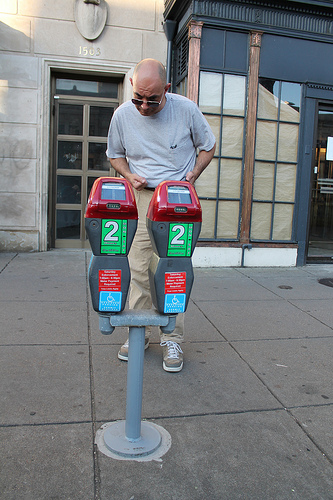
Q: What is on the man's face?
A: Sunglasses.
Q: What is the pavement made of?
A: Concrete.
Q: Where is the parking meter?
A: On the sidewalk.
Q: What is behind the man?
A: The building.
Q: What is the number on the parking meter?
A: 2.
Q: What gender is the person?
A: Male.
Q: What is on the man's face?
A: Sunglasses.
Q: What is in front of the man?
A: Parking meter.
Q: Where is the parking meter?
A: On the sidewalk.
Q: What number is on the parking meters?
A: 2.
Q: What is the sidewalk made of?
A: Concrete.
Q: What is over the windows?
A: Paper.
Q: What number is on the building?
A: 1563.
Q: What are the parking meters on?
A: Pole.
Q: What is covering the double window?
A: Brown paper.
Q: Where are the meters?
A: On the sidewalk.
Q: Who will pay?
A: The man.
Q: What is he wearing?
A: Glasses.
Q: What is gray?
A: His shirt.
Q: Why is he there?
A: To pay.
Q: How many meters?
A: 2.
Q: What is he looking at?
A: The meters.